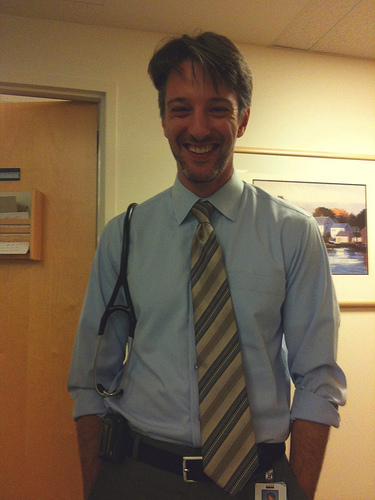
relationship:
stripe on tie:
[197, 256, 259, 488] [191, 207, 274, 481]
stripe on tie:
[184, 228, 201, 257] [188, 201, 265, 498]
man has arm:
[66, 28, 348, 500] [277, 215, 353, 498]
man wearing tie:
[66, 24, 353, 496] [188, 201, 265, 498]